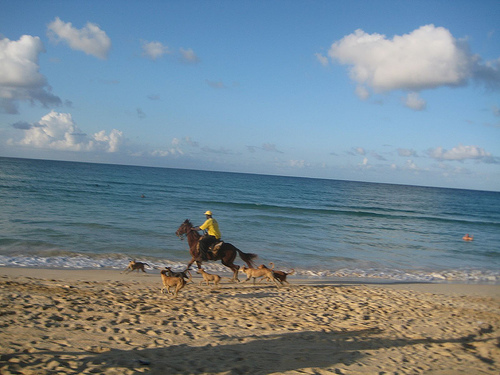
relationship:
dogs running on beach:
[96, 258, 302, 311] [9, 277, 420, 373]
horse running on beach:
[166, 206, 250, 274] [9, 277, 420, 373]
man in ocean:
[461, 231, 475, 243] [298, 194, 352, 220]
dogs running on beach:
[120, 249, 296, 299] [0, 260, 498, 373]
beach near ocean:
[0, 260, 498, 373] [4, 152, 498, 288]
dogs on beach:
[145, 229, 440, 316] [0, 260, 498, 373]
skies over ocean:
[1, 0, 486, 191] [4, 152, 498, 288]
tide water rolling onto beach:
[2, 248, 499, 289] [0, 260, 498, 373]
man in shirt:
[201, 202, 220, 244] [198, 216, 221, 240]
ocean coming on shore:
[0, 152, 497, 282] [9, 257, 498, 299]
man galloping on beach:
[191, 209, 220, 260] [0, 260, 498, 373]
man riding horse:
[191, 209, 220, 260] [172, 219, 258, 269]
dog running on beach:
[157, 263, 185, 298] [0, 260, 498, 373]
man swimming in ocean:
[461, 231, 475, 243] [82, 158, 470, 205]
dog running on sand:
[196, 265, 225, 293] [7, 257, 483, 351]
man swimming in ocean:
[461, 231, 475, 243] [1, 158, 498, 268]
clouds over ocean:
[3, 12, 498, 111] [66, 172, 417, 212]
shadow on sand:
[31, 322, 498, 373] [1, 266, 498, 373]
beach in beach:
[0, 260, 498, 373] [6, 244, 498, 373]